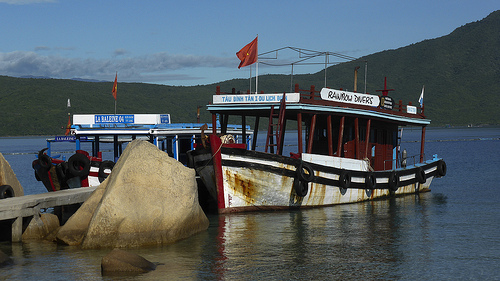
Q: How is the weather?
A: It is cloudy.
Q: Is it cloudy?
A: Yes, it is cloudy.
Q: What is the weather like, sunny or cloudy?
A: It is cloudy.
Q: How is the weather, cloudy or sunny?
A: It is cloudy.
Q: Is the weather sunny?
A: No, it is cloudy.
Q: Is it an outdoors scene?
A: Yes, it is outdoors.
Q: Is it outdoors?
A: Yes, it is outdoors.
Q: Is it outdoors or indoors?
A: It is outdoors.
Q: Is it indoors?
A: No, it is outdoors.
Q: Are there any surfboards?
A: No, there are no surfboards.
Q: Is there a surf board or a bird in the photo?
A: No, there are no surfboards or birds.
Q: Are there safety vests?
A: No, there are no safety vests.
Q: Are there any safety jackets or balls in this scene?
A: No, there are no safety jackets or balls.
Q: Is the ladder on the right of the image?
A: Yes, the ladder is on the right of the image.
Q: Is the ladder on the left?
A: No, the ladder is on the right of the image.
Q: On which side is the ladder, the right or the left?
A: The ladder is on the right of the image.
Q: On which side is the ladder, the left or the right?
A: The ladder is on the right of the image.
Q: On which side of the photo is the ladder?
A: The ladder is on the right of the image.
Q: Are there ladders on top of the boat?
A: Yes, there is a ladder on top of the boat.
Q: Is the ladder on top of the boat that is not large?
A: Yes, the ladder is on top of the boat.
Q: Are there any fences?
A: No, there are no fences.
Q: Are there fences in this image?
A: No, there are no fences.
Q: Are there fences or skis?
A: No, there are no fences or skis.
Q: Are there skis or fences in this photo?
A: No, there are no fences or skis.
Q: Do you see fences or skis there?
A: No, there are no fences or skis.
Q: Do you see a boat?
A: Yes, there is a boat.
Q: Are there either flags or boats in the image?
A: Yes, there is a boat.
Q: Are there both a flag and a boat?
A: Yes, there are both a boat and a flag.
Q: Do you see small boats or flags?
A: Yes, there is a small boat.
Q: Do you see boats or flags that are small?
A: Yes, the boat is small.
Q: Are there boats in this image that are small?
A: Yes, there is a small boat.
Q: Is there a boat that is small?
A: Yes, there is a boat that is small.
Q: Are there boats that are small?
A: Yes, there is a boat that is small.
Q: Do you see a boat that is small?
A: Yes, there is a boat that is small.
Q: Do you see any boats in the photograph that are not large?
A: Yes, there is a small boat.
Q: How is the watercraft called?
A: The watercraft is a boat.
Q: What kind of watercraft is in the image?
A: The watercraft is a boat.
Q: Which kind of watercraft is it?
A: The watercraft is a boat.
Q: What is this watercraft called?
A: This is a boat.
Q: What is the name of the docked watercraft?
A: The watercraft is a boat.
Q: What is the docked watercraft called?
A: The watercraft is a boat.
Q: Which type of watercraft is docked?
A: The watercraft is a boat.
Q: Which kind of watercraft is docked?
A: The watercraft is a boat.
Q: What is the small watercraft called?
A: The watercraft is a boat.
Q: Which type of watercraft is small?
A: The watercraft is a boat.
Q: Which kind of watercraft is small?
A: The watercraft is a boat.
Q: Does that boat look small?
A: Yes, the boat is small.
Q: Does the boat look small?
A: Yes, the boat is small.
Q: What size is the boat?
A: The boat is small.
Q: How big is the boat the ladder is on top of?
A: The boat is small.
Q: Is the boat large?
A: No, the boat is small.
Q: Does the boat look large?
A: No, the boat is small.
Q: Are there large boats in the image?
A: No, there is a boat but it is small.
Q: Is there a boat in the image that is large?
A: No, there is a boat but it is small.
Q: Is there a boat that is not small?
A: No, there is a boat but it is small.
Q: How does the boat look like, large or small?
A: The boat is small.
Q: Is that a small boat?
A: Yes, that is a small boat.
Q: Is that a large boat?
A: No, that is a small boat.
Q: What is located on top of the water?
A: The boat is on top of the water.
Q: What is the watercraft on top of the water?
A: The watercraft is a boat.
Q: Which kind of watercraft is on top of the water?
A: The watercraft is a boat.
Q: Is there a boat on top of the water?
A: Yes, there is a boat on top of the water.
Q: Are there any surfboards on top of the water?
A: No, there is a boat on top of the water.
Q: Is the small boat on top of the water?
A: Yes, the boat is on top of the water.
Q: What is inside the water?
A: The boat is inside the water.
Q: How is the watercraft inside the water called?
A: The watercraft is a boat.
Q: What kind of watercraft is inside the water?
A: The watercraft is a boat.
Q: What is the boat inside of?
A: The boat is inside the water.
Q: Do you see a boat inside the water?
A: Yes, there is a boat inside the water.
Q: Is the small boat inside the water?
A: Yes, the boat is inside the water.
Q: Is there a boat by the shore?
A: Yes, there is a boat by the shore.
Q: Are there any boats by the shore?
A: Yes, there is a boat by the shore.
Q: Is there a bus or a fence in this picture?
A: No, there are no fences or buses.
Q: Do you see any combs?
A: No, there are no combs.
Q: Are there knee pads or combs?
A: No, there are no combs or knee pads.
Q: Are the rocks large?
A: Yes, the rocks are large.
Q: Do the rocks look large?
A: Yes, the rocks are large.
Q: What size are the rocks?
A: The rocks are large.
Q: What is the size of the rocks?
A: The rocks are large.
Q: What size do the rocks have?
A: The rocks have large size.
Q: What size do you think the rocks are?
A: The rocks are large.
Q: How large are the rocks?
A: The rocks are large.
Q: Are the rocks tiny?
A: No, the rocks are large.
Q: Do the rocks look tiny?
A: No, the rocks are large.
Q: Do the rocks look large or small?
A: The rocks are large.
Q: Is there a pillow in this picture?
A: No, there are no pillows.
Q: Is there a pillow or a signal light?
A: No, there are no pillows or traffic lights.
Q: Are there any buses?
A: No, there are no buses.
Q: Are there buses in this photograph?
A: No, there are no buses.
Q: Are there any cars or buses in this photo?
A: No, there are no buses or cars.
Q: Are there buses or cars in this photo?
A: No, there are no buses or cars.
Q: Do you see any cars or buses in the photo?
A: No, there are no buses or cars.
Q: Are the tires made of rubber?
A: Yes, the tires are made of rubber.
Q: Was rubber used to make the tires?
A: Yes, the tires are made of rubber.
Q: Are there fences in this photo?
A: No, there are no fences.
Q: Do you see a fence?
A: No, there are no fences.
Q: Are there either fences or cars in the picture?
A: No, there are no fences or cars.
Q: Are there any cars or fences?
A: No, there are no fences or cars.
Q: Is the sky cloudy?
A: Yes, the sky is cloudy.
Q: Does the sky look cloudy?
A: Yes, the sky is cloudy.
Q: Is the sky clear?
A: No, the sky is cloudy.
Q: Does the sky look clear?
A: No, the sky is cloudy.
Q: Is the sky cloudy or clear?
A: The sky is cloudy.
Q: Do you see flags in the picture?
A: Yes, there is a flag.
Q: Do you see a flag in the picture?
A: Yes, there is a flag.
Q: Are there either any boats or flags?
A: Yes, there is a flag.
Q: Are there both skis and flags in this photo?
A: No, there is a flag but no skis.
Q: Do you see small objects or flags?
A: Yes, there is a small flag.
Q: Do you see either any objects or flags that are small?
A: Yes, the flag is small.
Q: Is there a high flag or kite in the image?
A: Yes, there is a high flag.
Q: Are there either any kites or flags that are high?
A: Yes, the flag is high.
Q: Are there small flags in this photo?
A: Yes, there is a small flag.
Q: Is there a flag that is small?
A: Yes, there is a flag that is small.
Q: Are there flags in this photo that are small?
A: Yes, there is a flag that is small.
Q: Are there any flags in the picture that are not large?
A: Yes, there is a small flag.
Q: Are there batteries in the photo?
A: No, there are no batteries.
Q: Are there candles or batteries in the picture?
A: No, there are no batteries or candles.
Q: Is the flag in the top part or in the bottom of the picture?
A: The flag is in the top of the image.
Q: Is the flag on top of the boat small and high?
A: Yes, the flag is small and high.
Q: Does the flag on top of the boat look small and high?
A: Yes, the flag is small and high.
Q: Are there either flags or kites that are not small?
A: No, there is a flag but it is small.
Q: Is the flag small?
A: Yes, the flag is small.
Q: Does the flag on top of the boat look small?
A: Yes, the flag is small.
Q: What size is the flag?
A: The flag is small.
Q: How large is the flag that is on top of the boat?
A: The flag is small.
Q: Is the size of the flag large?
A: No, the flag is small.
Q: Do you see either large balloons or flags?
A: No, there is a flag but it is small.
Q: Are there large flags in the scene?
A: No, there is a flag but it is small.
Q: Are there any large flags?
A: No, there is a flag but it is small.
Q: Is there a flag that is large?
A: No, there is a flag but it is small.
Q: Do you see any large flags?
A: No, there is a flag but it is small.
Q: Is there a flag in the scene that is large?
A: No, there is a flag but it is small.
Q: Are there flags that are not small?
A: No, there is a flag but it is small.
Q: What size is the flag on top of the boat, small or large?
A: The flag is small.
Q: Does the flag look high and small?
A: Yes, the flag is high and small.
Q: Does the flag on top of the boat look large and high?
A: No, the flag is high but small.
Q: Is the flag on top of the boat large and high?
A: No, the flag is high but small.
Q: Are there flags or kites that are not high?
A: No, there is a flag but it is high.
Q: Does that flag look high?
A: Yes, the flag is high.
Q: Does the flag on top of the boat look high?
A: Yes, the flag is high.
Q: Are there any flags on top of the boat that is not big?
A: Yes, there is a flag on top of the boat.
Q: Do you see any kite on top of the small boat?
A: No, there is a flag on top of the boat.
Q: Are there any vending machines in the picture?
A: No, there are no vending machines.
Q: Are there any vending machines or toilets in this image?
A: No, there are no vending machines or toilets.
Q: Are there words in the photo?
A: Yes, there are words.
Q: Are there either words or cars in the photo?
A: Yes, there are words.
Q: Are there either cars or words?
A: Yes, there are words.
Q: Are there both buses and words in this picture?
A: No, there are words but no buses.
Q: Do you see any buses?
A: No, there are no buses.